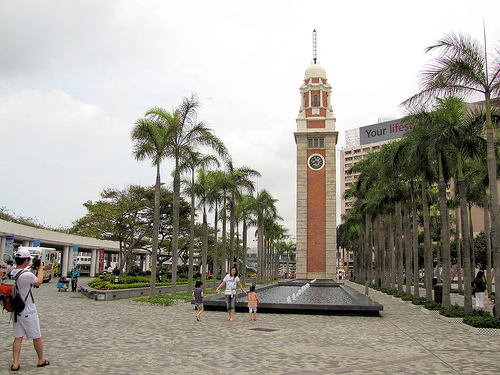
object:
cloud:
[0, 0, 499, 234]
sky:
[2, 2, 499, 215]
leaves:
[354, 32, 499, 206]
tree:
[397, 24, 499, 326]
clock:
[305, 151, 325, 171]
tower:
[292, 26, 341, 281]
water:
[224, 283, 353, 304]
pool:
[191, 277, 387, 317]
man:
[2, 246, 51, 371]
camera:
[30, 254, 44, 269]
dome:
[303, 65, 327, 83]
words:
[363, 122, 405, 139]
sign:
[358, 113, 415, 146]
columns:
[59, 247, 76, 279]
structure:
[0, 216, 206, 257]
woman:
[212, 266, 245, 322]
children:
[189, 280, 262, 321]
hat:
[15, 245, 34, 259]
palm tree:
[132, 99, 178, 306]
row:
[342, 23, 499, 333]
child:
[190, 276, 207, 323]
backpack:
[0, 268, 29, 316]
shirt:
[69, 267, 79, 281]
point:
[308, 27, 322, 65]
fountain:
[275, 273, 323, 305]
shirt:
[222, 273, 241, 296]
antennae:
[311, 28, 320, 64]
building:
[338, 98, 499, 283]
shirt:
[245, 291, 260, 305]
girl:
[245, 285, 259, 321]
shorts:
[247, 307, 260, 316]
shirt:
[192, 288, 206, 304]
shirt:
[8, 269, 38, 312]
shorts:
[12, 307, 43, 340]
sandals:
[8, 360, 53, 370]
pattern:
[79, 333, 152, 363]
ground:
[2, 274, 499, 373]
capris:
[226, 294, 236, 312]